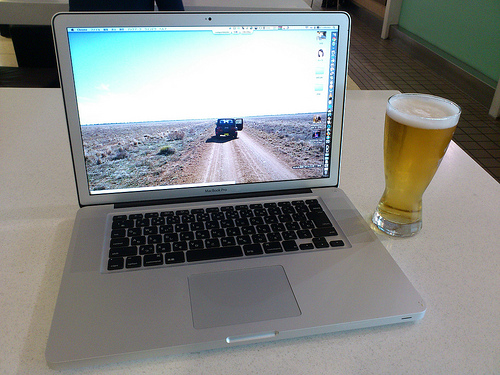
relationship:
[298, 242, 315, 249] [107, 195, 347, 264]
button on keyboard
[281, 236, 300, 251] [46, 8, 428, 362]
button on keyboard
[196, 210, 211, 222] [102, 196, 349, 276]
button on keyboard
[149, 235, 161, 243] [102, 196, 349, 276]
button on keyboard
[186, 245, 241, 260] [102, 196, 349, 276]
button on keyboard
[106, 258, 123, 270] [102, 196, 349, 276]
button on keyboard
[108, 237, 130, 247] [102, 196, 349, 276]
button on keyboard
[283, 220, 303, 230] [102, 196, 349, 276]
button on keyboard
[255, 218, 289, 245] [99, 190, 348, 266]
button on keyboard